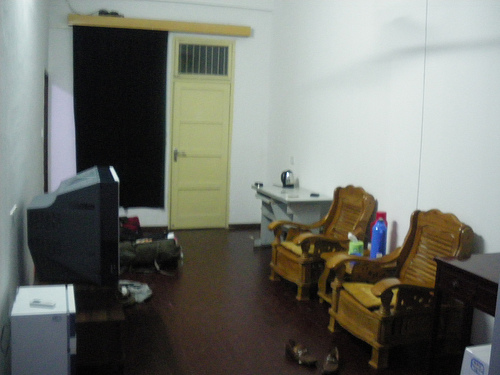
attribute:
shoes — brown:
[286, 331, 351, 365]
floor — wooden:
[34, 226, 472, 374]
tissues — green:
[345, 236, 365, 256]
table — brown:
[320, 254, 412, 269]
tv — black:
[23, 170, 125, 303]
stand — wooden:
[65, 297, 130, 366]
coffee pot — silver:
[281, 168, 298, 188]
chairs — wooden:
[275, 191, 457, 333]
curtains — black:
[74, 28, 166, 205]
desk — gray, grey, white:
[255, 181, 323, 243]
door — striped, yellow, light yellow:
[174, 78, 227, 228]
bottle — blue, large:
[369, 217, 386, 262]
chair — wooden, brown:
[277, 187, 368, 281]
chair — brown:
[340, 218, 461, 340]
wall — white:
[273, 8, 498, 260]